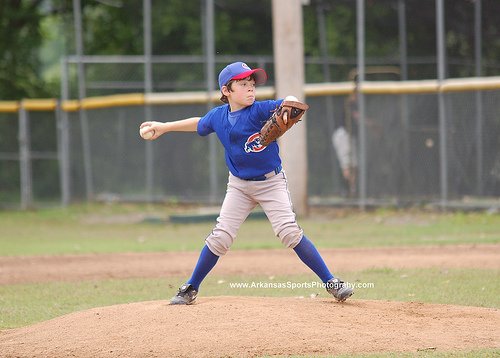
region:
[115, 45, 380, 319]
young boy throwing the ball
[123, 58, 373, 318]
pitcher on the mound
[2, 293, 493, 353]
small mound of dirt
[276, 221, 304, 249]
wrinkles in the fabric of the pants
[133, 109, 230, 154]
arm extended behind the body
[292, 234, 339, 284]
long blue sock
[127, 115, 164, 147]
fingers gripping the baseball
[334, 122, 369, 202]
person standing behind the fence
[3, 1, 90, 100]
trees poking over the top of the fence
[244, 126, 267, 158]
logo on the shirt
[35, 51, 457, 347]
Boy is playing base ball.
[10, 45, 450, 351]
Boy is standing on the pitcher's mount.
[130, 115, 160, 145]
Boy is pitching the ball.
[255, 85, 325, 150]
Boy is wearing a baseball mitt.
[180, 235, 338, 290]
Boy is wearing knee length blue socks.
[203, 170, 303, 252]
Boy is wearing biege baseball pants.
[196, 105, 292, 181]
Boy is wearing a blue shirt.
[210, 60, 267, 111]
Boy is wearing a blue and white hat.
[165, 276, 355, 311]
Boy is wearing baseball shoes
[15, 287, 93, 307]
The grass is green.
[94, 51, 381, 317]
a boy wearing a baseball uniform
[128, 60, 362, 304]
a boy about to throw a baseball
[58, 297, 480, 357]
brown dirt of the pitcher's mound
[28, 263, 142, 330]
green grass of the baseball field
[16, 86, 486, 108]
yellow fenceguard in the background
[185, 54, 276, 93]
the boy's blue and red hat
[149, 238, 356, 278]
the boy's blue socks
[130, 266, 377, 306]
the boy's black baseball cletes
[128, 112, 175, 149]
a baseball in the boys hand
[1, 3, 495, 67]
fence surrounding the baseball field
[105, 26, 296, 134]
boy is throwing a ball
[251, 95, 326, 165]
boy is wearing baseball mitt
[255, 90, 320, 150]
baseball mitt is brown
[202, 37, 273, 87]
hat is red and blue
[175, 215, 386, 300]
the socks are blue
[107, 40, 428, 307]
boy is standing on baseball field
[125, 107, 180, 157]
the ball is in boy's right hand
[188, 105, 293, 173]
boy's shirt is blue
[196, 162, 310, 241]
boy's pants are white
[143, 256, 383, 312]
boy's shoes are black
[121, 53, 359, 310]
little boy throwing a ball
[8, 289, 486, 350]
small mound of light brown dirt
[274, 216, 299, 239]
wrinkles in the pants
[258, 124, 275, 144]
black seams on the brown glove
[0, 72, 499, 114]
top of the fence is yellow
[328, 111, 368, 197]
person standing by the fence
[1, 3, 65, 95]
tree peaking over the chain link fence